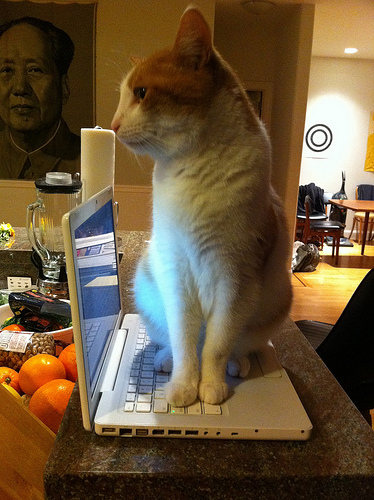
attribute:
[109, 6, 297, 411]
cat — white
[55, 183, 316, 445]
laptop — white, open, on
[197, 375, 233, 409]
paw — white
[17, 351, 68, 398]
orange — shiny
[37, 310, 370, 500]
counter top — granite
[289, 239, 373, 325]
floor — wood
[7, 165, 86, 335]
blender — glass, black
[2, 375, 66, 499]
basket — wooden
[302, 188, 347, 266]
chair — wooden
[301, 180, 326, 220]
jacket — black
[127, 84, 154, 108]
eye — gold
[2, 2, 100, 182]
portrait — mao, asian man